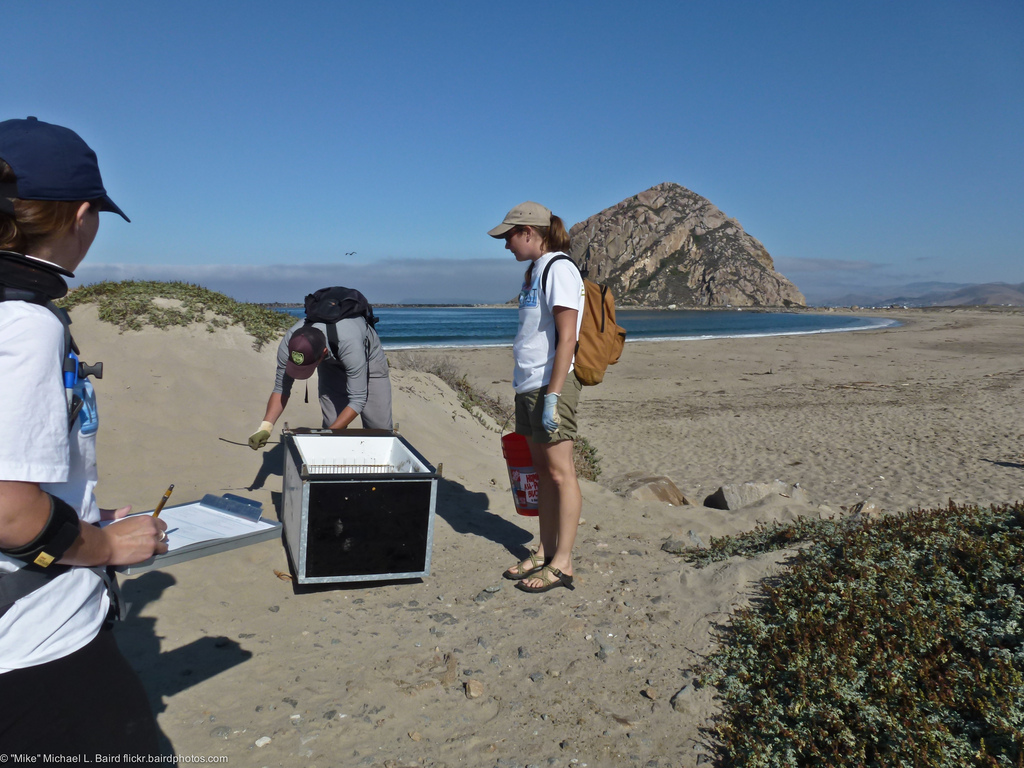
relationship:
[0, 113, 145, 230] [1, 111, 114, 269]
hat on head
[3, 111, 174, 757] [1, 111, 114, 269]
woman has head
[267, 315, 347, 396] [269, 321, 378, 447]
hat on person's head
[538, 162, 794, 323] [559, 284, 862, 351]
rock in water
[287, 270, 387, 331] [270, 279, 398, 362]
backpack on man's back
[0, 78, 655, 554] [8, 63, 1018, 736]
people on beach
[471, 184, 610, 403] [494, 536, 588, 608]
girl wearing sandals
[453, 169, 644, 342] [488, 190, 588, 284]
girl wearing cap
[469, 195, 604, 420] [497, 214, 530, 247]
girl wearing a glasses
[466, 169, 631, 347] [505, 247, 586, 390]
girl wearing a shirt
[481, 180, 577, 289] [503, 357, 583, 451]
girl wearing shorts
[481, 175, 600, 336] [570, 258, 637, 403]
girl wearing a backpack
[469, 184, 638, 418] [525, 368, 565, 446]
girl wearing gloves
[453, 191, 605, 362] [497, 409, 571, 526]
girl holding bucket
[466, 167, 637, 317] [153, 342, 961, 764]
girl standing on beach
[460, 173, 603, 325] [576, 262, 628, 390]
woman carrying a bucket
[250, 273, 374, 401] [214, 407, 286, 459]
man gathering samples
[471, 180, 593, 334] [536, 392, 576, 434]
woman wearing gloves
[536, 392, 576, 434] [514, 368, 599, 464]
gloves on hands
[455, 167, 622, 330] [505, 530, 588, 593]
woman wearing sandals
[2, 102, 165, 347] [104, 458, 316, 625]
person holding clipboard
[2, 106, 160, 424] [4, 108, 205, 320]
person wearing hat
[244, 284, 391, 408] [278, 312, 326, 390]
man wearing hat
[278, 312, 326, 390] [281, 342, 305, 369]
hat with logo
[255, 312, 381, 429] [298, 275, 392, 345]
man wearing backpack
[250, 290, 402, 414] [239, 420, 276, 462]
man wearing gloves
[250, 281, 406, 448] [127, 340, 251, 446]
man standing in tan sand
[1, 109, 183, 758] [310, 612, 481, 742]
man standing in tan sand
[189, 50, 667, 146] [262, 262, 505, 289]
sky with clouds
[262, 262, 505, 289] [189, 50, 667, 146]
clouds in sky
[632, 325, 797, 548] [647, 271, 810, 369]
sand on beach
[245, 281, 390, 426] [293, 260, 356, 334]
person with a backpack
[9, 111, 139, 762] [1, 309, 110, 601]
person in a shirt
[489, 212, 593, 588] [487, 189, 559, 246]
person wearing a cap